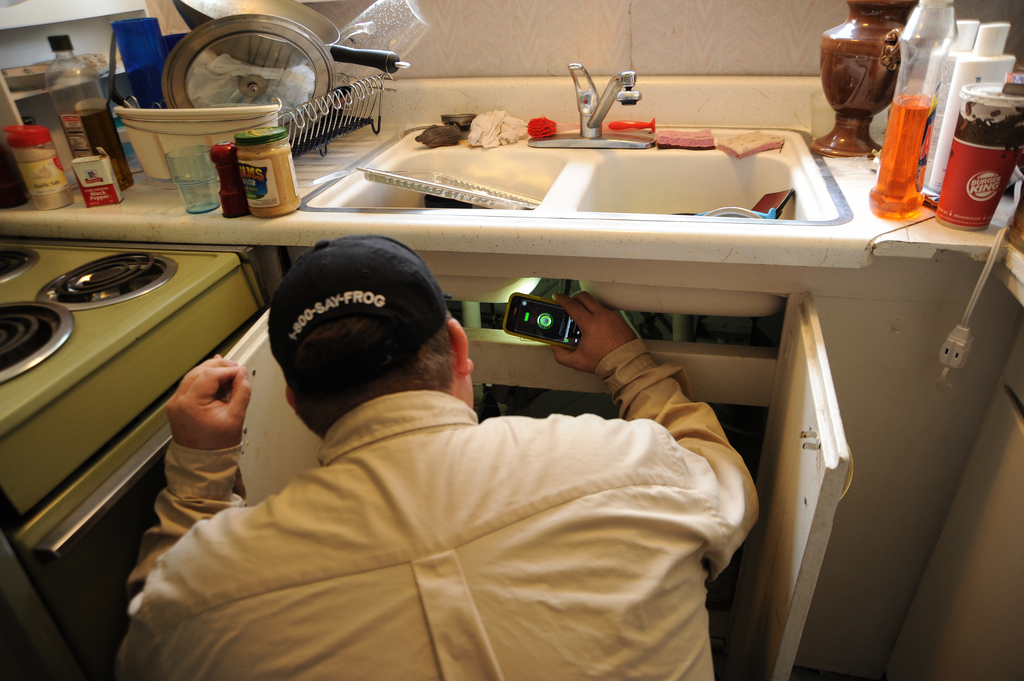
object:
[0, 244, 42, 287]
burner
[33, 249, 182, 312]
burner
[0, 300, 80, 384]
burner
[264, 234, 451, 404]
cap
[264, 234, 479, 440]
head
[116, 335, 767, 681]
white shirt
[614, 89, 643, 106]
sink spout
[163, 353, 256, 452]
hand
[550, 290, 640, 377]
hand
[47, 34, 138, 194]
items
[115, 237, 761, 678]
man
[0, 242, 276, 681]
green stove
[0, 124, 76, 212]
spice container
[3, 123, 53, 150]
red lid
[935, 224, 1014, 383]
extension cord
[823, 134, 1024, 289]
counter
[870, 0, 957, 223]
plastic bottle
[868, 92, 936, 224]
dish soap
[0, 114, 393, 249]
counter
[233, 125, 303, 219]
jar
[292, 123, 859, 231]
sink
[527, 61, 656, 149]
faucet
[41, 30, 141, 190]
bottle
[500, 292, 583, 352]
phone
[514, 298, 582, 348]
lights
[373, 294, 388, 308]
numbers letters